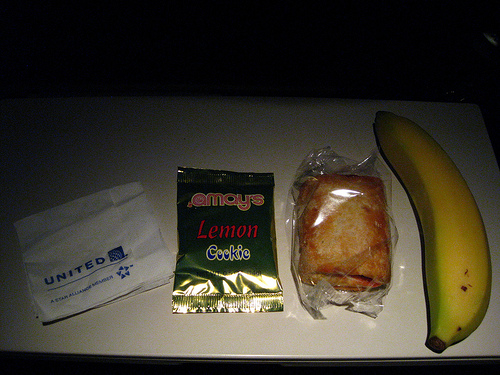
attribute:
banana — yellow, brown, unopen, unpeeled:
[371, 108, 495, 355]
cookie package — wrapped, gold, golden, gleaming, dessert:
[172, 165, 291, 320]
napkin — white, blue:
[10, 175, 181, 330]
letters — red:
[195, 219, 257, 241]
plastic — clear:
[287, 142, 402, 321]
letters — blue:
[39, 255, 106, 288]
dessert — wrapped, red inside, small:
[289, 143, 395, 322]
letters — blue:
[205, 243, 251, 264]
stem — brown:
[425, 336, 451, 356]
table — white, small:
[2, 87, 499, 369]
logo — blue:
[107, 244, 126, 264]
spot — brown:
[457, 283, 468, 296]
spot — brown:
[455, 324, 463, 334]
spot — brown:
[462, 265, 470, 277]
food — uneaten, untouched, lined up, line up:
[11, 106, 489, 354]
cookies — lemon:
[176, 166, 291, 306]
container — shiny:
[174, 160, 284, 309]